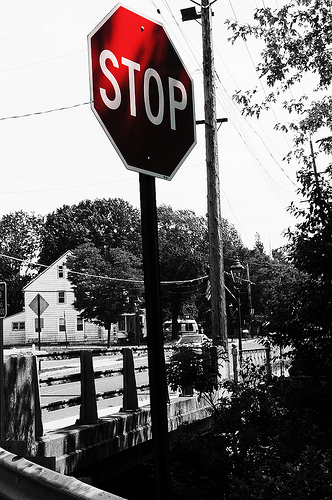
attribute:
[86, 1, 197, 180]
stop sign — red, eight sided, white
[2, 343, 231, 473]
bridge — for vehicle traffic, short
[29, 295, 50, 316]
back — of traffic sign, turned away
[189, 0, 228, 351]
telephone pole — large, tall, rough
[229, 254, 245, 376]
street light — old fashioned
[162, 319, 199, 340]
van — parked, camper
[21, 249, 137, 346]
house — three story, very large, white, white clapboard, nice, white wooden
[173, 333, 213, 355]
car — parked, white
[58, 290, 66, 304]
window — open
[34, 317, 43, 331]
street sign — turned away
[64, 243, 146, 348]
tree — large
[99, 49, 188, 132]
word — stop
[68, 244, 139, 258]
edge — scalloped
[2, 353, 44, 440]
column support — concrete